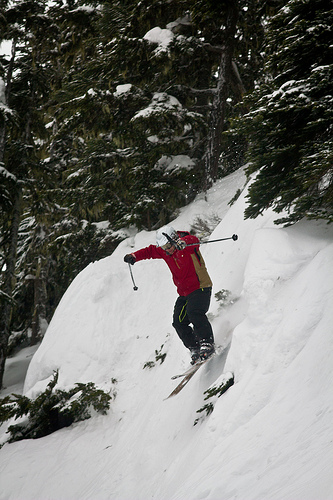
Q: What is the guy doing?
A: Skiing.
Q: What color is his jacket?
A: Red.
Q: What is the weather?
A: Snowing.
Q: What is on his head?
A: A helmet.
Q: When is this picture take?
A: In the winter.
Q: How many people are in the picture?
A: 1.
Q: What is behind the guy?
A: Trees.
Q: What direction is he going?
A: Down.